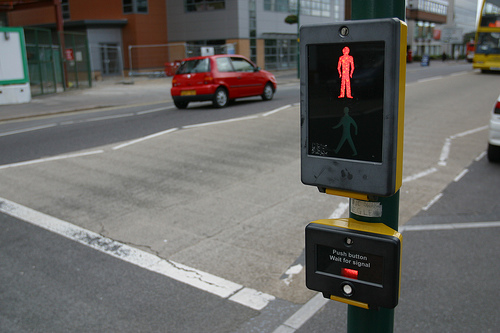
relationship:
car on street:
[132, 37, 296, 163] [0, 53, 495, 329]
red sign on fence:
[62, 41, 79, 64] [21, 27, 96, 101]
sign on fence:
[61, 47, 73, 61] [21, 27, 92, 96]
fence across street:
[21, 27, 92, 96] [0, 53, 495, 329]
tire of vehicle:
[486, 145, 499, 167] [488, 89, 498, 164]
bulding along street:
[4, 5, 174, 77] [102, 133, 284, 263]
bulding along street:
[398, 0, 467, 64] [102, 133, 284, 263]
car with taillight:
[170, 53, 277, 108] [494, 100, 499, 114]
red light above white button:
[340, 265, 358, 277] [341, 283, 351, 295]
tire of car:
[262, 82, 274, 99] [170, 53, 277, 108]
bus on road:
[467, 2, 499, 68] [0, 63, 490, 324]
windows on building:
[413, 0, 453, 17] [169, 3, 490, 82]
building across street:
[169, 3, 490, 82] [0, 53, 495, 329]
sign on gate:
[62, 49, 74, 61] [32, 39, 107, 97]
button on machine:
[342, 283, 354, 295] [306, 219, 400, 310]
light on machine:
[338, 261, 362, 281] [304, 211, 404, 315]